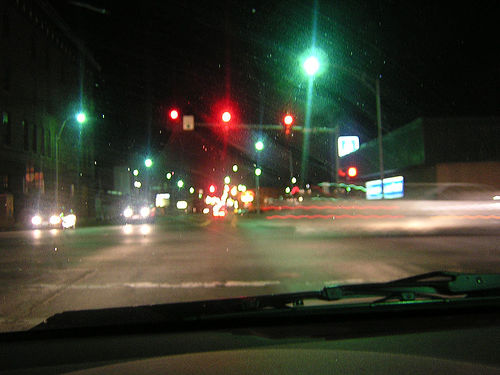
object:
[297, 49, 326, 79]
light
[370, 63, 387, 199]
pole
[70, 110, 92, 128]
light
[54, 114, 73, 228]
pole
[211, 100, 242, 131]
light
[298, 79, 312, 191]
pole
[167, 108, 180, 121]
light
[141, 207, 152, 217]
light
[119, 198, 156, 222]
car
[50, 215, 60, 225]
light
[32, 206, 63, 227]
car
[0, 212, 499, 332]
street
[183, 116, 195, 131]
sign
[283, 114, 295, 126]
light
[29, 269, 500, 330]
windshield wiper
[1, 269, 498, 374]
car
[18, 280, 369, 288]
line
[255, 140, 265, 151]
light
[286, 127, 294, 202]
pole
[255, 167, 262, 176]
light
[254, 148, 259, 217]
pole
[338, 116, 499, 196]
building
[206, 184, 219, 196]
lights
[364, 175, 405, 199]
sign